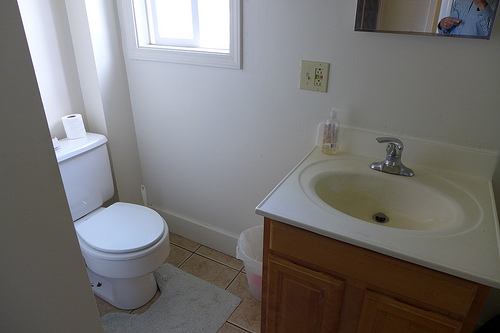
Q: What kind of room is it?
A: It is a bathroom.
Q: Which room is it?
A: It is a bathroom.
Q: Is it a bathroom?
A: Yes, it is a bathroom.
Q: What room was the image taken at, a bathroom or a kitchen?
A: It was taken at a bathroom.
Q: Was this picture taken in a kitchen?
A: No, the picture was taken in a bathroom.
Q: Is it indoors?
A: Yes, it is indoors.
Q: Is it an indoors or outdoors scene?
A: It is indoors.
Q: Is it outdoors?
A: No, it is indoors.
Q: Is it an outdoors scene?
A: No, it is indoors.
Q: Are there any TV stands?
A: No, there are no TV stands.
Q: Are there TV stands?
A: No, there are no TV stands.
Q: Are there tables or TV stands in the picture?
A: No, there are no TV stands or tables.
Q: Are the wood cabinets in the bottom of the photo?
A: Yes, the cabinets are in the bottom of the image.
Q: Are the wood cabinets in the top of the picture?
A: No, the cabinets are in the bottom of the image.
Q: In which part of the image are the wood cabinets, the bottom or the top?
A: The cabinets are in the bottom of the image.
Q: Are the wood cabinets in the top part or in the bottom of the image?
A: The cabinets are in the bottom of the image.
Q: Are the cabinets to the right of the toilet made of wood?
A: Yes, the cabinets are made of wood.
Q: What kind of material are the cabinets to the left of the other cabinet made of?
A: The cabinets are made of wood.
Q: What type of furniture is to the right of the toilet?
A: The pieces of furniture are cabinets.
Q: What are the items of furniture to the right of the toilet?
A: The pieces of furniture are cabinets.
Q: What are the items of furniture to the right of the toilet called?
A: The pieces of furniture are cabinets.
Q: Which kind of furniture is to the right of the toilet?
A: The pieces of furniture are cabinets.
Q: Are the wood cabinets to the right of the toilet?
A: Yes, the cabinets are to the right of the toilet.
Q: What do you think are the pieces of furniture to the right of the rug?
A: The pieces of furniture are cabinets.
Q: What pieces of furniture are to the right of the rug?
A: The pieces of furniture are cabinets.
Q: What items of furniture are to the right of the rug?
A: The pieces of furniture are cabinets.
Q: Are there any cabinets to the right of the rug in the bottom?
A: Yes, there are cabinets to the right of the rug.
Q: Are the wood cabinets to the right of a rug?
A: Yes, the cabinets are to the right of a rug.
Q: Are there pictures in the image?
A: No, there are no pictures.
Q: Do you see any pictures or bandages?
A: No, there are no pictures or bandages.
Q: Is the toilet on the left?
A: Yes, the toilet is on the left of the image.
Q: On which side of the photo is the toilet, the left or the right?
A: The toilet is on the left of the image.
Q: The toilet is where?
A: The toilet is in the bathroom.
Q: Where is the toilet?
A: The toilet is in the bathroom.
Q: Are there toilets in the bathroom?
A: Yes, there is a toilet in the bathroom.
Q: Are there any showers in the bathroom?
A: No, there is a toilet in the bathroom.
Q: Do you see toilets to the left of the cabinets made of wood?
A: Yes, there is a toilet to the left of the cabinets.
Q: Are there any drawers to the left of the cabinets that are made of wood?
A: No, there is a toilet to the left of the cabinets.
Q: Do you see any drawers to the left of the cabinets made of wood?
A: No, there is a toilet to the left of the cabinets.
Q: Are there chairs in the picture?
A: No, there are no chairs.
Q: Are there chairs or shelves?
A: No, there are no chairs or shelves.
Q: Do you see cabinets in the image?
A: Yes, there is a cabinet.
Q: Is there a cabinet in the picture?
A: Yes, there is a cabinet.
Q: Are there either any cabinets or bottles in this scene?
A: Yes, there is a cabinet.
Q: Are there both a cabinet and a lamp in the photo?
A: No, there is a cabinet but no lamps.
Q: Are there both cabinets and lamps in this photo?
A: No, there is a cabinet but no lamps.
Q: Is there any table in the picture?
A: No, there are no tables.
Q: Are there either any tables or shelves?
A: No, there are no tables or shelves.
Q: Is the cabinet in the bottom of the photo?
A: Yes, the cabinet is in the bottom of the image.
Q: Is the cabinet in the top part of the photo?
A: No, the cabinet is in the bottom of the image.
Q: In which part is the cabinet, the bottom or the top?
A: The cabinet is in the bottom of the image.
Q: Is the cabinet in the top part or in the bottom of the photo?
A: The cabinet is in the bottom of the image.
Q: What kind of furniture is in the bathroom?
A: The piece of furniture is a cabinet.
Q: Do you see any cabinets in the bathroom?
A: Yes, there is a cabinet in the bathroom.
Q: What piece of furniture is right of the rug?
A: The piece of furniture is a cabinet.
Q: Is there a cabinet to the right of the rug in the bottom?
A: Yes, there is a cabinet to the right of the rug.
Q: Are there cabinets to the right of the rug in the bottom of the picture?
A: Yes, there is a cabinet to the right of the rug.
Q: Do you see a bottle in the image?
A: Yes, there is a bottle.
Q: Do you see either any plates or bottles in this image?
A: Yes, there is a bottle.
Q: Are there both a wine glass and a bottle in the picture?
A: No, there is a bottle but no wine glasses.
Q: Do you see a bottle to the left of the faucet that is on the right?
A: Yes, there is a bottle to the left of the faucet.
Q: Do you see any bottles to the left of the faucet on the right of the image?
A: Yes, there is a bottle to the left of the faucet.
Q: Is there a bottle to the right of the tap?
A: No, the bottle is to the left of the tap.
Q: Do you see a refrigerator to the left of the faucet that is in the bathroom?
A: No, there is a bottle to the left of the faucet.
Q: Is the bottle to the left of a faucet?
A: Yes, the bottle is to the left of a faucet.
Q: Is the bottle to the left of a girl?
A: No, the bottle is to the left of a faucet.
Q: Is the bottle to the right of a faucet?
A: No, the bottle is to the left of a faucet.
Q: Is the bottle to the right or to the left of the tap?
A: The bottle is to the left of the tap.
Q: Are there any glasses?
A: No, there are no glasses.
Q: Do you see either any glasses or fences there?
A: No, there are no glasses or fences.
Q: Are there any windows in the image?
A: Yes, there is a window.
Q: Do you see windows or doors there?
A: Yes, there is a window.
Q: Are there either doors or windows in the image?
A: Yes, there is a window.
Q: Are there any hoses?
A: No, there are no hoses.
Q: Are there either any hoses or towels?
A: No, there are no hoses or towels.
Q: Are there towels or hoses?
A: No, there are no hoses or towels.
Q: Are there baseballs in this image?
A: No, there are no baseballs.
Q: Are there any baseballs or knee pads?
A: No, there are no baseballs or knee pads.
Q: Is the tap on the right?
A: Yes, the tap is on the right of the image.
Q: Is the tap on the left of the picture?
A: No, the tap is on the right of the image.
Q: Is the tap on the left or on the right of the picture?
A: The tap is on the right of the image.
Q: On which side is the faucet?
A: The faucet is on the right of the image.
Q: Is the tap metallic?
A: Yes, the tap is metallic.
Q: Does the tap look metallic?
A: Yes, the tap is metallic.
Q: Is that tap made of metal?
A: Yes, the tap is made of metal.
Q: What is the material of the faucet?
A: The faucet is made of metal.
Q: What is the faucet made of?
A: The faucet is made of metal.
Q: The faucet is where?
A: The faucet is in the bathroom.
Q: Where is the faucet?
A: The faucet is in the bathroom.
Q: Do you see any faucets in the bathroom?
A: Yes, there is a faucet in the bathroom.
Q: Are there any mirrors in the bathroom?
A: No, there is a faucet in the bathroom.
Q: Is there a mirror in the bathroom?
A: No, there is a faucet in the bathroom.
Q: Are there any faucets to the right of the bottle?
A: Yes, there is a faucet to the right of the bottle.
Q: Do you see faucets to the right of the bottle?
A: Yes, there is a faucet to the right of the bottle.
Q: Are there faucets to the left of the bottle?
A: No, the faucet is to the right of the bottle.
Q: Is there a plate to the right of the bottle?
A: No, there is a faucet to the right of the bottle.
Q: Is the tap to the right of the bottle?
A: Yes, the tap is to the right of the bottle.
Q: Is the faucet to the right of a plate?
A: No, the faucet is to the right of the bottle.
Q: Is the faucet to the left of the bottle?
A: No, the faucet is to the right of the bottle.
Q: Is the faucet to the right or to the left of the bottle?
A: The faucet is to the right of the bottle.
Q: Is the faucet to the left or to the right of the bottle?
A: The faucet is to the right of the bottle.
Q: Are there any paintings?
A: No, there are no paintings.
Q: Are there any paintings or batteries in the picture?
A: No, there are no paintings or batteries.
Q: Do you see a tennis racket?
A: No, there are no rackets.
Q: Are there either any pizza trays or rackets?
A: No, there are no rackets or pizza trays.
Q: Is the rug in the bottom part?
A: Yes, the rug is in the bottom of the image.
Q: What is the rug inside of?
A: The rug is inside the bathroom.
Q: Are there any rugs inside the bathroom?
A: Yes, there is a rug inside the bathroom.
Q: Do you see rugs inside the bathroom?
A: Yes, there is a rug inside the bathroom.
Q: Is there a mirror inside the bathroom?
A: No, there is a rug inside the bathroom.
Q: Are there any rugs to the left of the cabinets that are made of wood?
A: Yes, there is a rug to the left of the cabinets.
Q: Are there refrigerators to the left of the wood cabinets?
A: No, there is a rug to the left of the cabinets.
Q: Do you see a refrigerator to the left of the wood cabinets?
A: No, there is a rug to the left of the cabinets.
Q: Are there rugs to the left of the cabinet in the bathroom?
A: Yes, there is a rug to the left of the cabinet.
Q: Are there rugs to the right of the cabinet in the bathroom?
A: No, the rug is to the left of the cabinet.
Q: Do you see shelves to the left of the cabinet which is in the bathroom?
A: No, there is a rug to the left of the cabinet.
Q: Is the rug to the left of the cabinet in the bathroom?
A: Yes, the rug is to the left of the cabinet.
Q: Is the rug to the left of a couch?
A: No, the rug is to the left of the cabinet.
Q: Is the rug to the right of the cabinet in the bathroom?
A: No, the rug is to the left of the cabinet.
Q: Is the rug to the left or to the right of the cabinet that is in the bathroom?
A: The rug is to the left of the cabinet.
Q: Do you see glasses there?
A: No, there are no glasses.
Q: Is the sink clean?
A: Yes, the sink is clean.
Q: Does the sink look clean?
A: Yes, the sink is clean.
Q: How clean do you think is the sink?
A: The sink is clean.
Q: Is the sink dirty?
A: No, the sink is clean.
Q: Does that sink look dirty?
A: No, the sink is clean.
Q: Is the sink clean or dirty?
A: The sink is clean.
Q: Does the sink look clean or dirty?
A: The sink is clean.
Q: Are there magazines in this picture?
A: No, there are no magazines.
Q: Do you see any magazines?
A: No, there are no magazines.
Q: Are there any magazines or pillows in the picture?
A: No, there are no magazines or pillows.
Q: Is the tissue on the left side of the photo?
A: Yes, the tissue is on the left of the image.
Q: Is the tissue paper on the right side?
A: No, the tissue paper is on the left of the image.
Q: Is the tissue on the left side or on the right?
A: The tissue is on the left of the image.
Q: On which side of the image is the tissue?
A: The tissue is on the left of the image.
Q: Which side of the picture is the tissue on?
A: The tissue is on the left of the image.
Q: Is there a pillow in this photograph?
A: No, there are no pillows.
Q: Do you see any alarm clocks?
A: No, there are no alarm clocks.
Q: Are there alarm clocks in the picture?
A: No, there are no alarm clocks.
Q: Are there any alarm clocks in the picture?
A: No, there are no alarm clocks.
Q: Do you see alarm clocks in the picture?
A: No, there are no alarm clocks.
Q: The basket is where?
A: The basket is in the bathroom.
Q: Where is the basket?
A: The basket is in the bathroom.